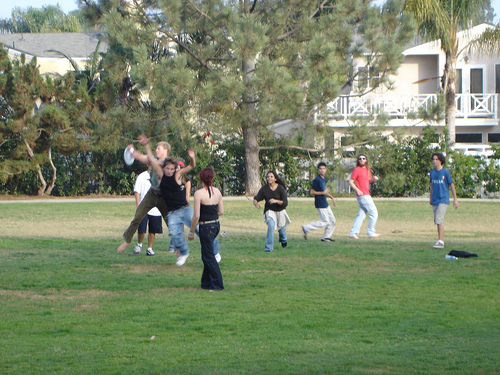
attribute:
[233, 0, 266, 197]
tree branch — gray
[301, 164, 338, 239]
kid — red shirted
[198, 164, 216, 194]
hair — red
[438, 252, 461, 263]
bottle — plastic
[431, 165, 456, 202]
shirt — blue 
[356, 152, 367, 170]
hair — long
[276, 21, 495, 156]
house — white 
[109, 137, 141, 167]
frisbee — white 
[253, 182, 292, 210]
shirt — long sleeve black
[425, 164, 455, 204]
shirt — short sleeve, blue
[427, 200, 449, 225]
shorts — khaki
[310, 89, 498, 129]
balcony — long, white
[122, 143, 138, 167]
frisbee — large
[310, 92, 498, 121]
railing — white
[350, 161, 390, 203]
shirt — red, short sleeve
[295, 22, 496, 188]
house — large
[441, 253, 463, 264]
bottle — water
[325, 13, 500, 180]
house — white 